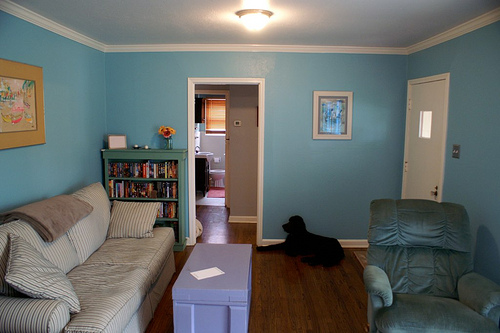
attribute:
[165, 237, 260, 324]
table — gray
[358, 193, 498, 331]
chair — large and plush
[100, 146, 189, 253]
bookcase — turquois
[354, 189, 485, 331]
recliner — blue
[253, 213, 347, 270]
dog — black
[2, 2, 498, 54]
ceiling — white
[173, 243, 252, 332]
table — plastic, coffee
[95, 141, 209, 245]
bookcase — green, filled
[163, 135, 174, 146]
vase — with yellow flowers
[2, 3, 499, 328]
room — living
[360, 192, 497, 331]
seat — light green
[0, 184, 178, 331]
stripes — dark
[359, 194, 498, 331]
recliner — blue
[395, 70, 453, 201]
door — white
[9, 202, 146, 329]
couch — tan, striped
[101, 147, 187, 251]
bookshelf — green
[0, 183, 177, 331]
couch — white 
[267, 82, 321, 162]
walls — blue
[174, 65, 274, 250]
door frame — white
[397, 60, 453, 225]
door frame — white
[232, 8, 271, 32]
light — bright